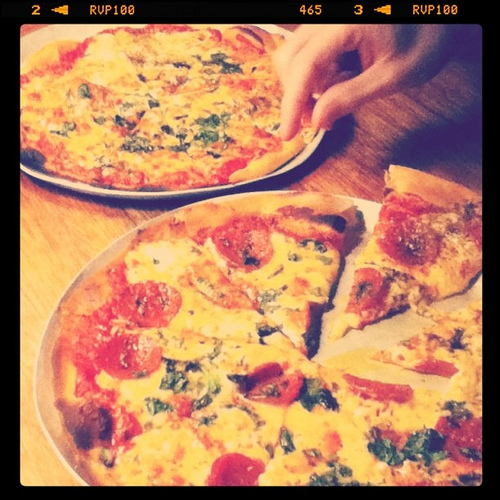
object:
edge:
[20, 165, 143, 200]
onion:
[97, 405, 110, 445]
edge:
[156, 179, 252, 203]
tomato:
[344, 370, 416, 405]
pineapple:
[284, 393, 313, 431]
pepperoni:
[390, 217, 438, 266]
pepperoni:
[120, 281, 182, 328]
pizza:
[38, 160, 483, 487]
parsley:
[302, 375, 337, 407]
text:
[29, 0, 138, 19]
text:
[295, 0, 463, 19]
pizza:
[18, 22, 323, 194]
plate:
[16, 20, 333, 197]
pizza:
[20, 24, 319, 193]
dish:
[19, 22, 345, 200]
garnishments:
[138, 353, 426, 424]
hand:
[268, 25, 464, 145]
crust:
[18, 165, 483, 491]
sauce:
[85, 160, 233, 190]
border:
[2, 2, 498, 496]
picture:
[18, 20, 488, 486]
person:
[263, 21, 457, 141]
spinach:
[358, 424, 453, 470]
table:
[17, 22, 485, 486]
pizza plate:
[27, 178, 482, 486]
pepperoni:
[209, 212, 269, 268]